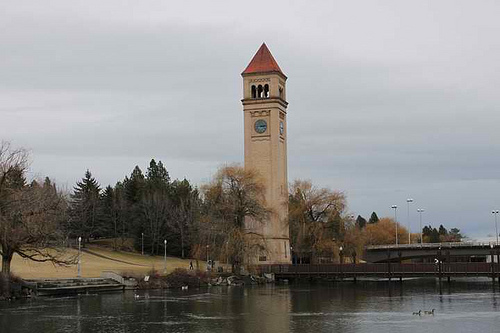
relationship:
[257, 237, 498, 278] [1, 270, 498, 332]
bridge over water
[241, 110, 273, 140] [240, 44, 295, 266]
clock in tower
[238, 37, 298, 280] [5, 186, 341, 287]
building in park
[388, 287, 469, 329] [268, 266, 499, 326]
ducks swimming in water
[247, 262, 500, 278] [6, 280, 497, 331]
bridge over water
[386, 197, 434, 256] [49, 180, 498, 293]
street lights in park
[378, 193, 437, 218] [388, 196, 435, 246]
lamps on poles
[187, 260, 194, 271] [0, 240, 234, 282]
man in park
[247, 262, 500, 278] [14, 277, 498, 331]
bridge extending over lake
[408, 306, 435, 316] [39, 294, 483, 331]
ducks on lake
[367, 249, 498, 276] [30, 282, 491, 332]
bridge spanning lake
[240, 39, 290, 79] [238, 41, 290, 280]
roof on tower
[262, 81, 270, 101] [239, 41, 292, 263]
window on building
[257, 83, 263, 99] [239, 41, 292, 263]
window on building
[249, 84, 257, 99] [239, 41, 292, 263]
window on building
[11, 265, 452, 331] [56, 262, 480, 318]
water in lake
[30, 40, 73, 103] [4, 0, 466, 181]
white clouds in sky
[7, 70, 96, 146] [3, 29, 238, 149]
clouds in sky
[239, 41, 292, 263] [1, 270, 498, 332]
building by water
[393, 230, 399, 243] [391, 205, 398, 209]
bottom of street lights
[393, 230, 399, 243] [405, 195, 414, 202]
bottom of lamp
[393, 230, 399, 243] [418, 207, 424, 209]
bottom of lamp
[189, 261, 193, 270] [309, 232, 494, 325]
man walking around